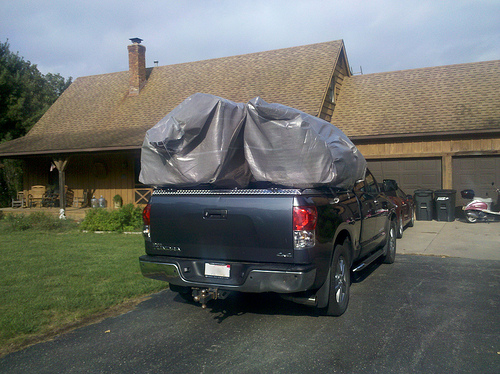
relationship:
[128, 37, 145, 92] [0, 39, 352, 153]
chimney has roof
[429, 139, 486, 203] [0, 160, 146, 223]
column on porch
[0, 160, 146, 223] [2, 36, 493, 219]
porch from home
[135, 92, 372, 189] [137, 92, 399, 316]
tarp in blue truck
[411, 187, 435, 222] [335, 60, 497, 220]
trash barrel in front of garage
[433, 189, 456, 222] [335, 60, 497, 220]
cans in front of garage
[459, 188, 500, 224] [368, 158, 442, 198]
motorcycle in front of door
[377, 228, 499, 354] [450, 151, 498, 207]
driveway in front of garage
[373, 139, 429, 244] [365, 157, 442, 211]
car parked in front of garage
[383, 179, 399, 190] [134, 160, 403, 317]
mirror on pick up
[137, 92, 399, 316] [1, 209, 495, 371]
blue truck parked in driveway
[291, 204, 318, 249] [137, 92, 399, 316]
brakelights on back of blue truck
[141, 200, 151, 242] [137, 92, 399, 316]
brakelights on back of blue truck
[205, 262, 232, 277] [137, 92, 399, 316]
license on blue truck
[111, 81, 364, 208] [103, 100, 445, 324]
cargo on back of truck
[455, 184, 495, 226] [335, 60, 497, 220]
motorcycle in front of garage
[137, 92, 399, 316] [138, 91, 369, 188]
blue truck loading covered object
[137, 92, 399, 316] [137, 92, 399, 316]
blue truck behind blue truck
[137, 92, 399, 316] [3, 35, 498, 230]
blue truck in front of house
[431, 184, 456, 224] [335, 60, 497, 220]
cans near garage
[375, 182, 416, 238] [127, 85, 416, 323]
car in front of truck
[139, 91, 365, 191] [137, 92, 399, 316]
object onto blue truck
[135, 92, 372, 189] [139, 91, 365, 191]
tarp covering object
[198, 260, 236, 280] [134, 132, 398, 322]
tag on back of truck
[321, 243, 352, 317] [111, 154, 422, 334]
tire on truck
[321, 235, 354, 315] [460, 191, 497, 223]
tire on scooter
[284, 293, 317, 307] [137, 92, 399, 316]
muffler on blue truck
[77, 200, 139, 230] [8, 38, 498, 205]
bushes in front of house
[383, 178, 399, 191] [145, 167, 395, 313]
mirror on side of truck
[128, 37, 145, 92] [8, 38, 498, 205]
chimney on house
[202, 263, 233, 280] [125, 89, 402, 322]
license plate on back of blue truck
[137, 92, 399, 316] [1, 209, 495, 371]
blue truck in driveway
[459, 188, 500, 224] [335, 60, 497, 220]
motorcycle in front of garage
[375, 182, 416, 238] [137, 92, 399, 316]
car in front of blue truck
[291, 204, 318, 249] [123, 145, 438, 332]
brakelights on truck